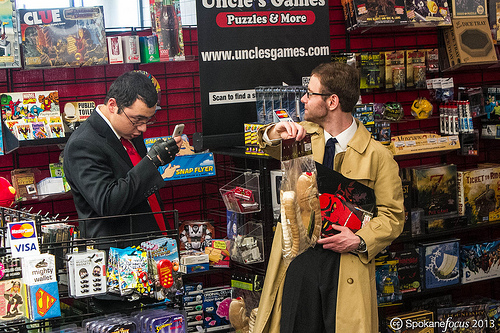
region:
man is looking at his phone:
[63, 71, 184, 241]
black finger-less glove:
[148, 138, 180, 166]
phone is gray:
[173, 121, 185, 136]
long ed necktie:
[121, 135, 170, 229]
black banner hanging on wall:
[196, 1, 333, 151]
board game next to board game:
[458, 168, 498, 229]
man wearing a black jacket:
[64, 74, 172, 246]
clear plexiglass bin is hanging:
[219, 170, 264, 215]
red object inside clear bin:
[233, 186, 253, 204]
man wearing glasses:
[61, 72, 171, 242]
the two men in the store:
[62, 60, 404, 331]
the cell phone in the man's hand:
[172, 123, 184, 137]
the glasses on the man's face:
[112, 98, 157, 126]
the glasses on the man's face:
[303, 87, 338, 98]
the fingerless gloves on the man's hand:
[147, 138, 179, 167]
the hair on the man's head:
[310, 60, 360, 110]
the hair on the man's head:
[105, 70, 159, 114]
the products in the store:
[0, 0, 498, 331]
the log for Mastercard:
[8, 221, 34, 237]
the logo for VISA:
[10, 240, 36, 252]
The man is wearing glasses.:
[253, 51, 408, 263]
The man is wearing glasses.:
[53, 63, 193, 232]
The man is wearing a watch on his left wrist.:
[253, 58, 403, 264]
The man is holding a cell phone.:
[63, 57, 194, 225]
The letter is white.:
[196, 45, 213, 65]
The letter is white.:
[233, 46, 243, 61]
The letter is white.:
[239, 45, 248, 61]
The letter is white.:
[247, 47, 254, 60]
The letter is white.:
[270, 45, 278, 65]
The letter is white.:
[275, 45, 285, 61]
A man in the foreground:
[224, 40, 409, 331]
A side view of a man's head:
[296, 48, 364, 141]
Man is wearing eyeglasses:
[297, 83, 336, 105]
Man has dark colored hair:
[301, 53, 373, 122]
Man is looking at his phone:
[57, 66, 202, 248]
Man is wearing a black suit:
[55, 101, 194, 249]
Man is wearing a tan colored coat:
[243, 99, 407, 331]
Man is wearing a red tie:
[115, 133, 180, 241]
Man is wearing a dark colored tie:
[315, 133, 343, 173]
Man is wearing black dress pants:
[278, 243, 350, 331]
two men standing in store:
[20, 0, 485, 329]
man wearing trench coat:
[235, 120, 397, 329]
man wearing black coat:
[51, 95, 158, 255]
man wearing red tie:
[111, 113, 167, 242]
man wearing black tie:
[305, 132, 342, 199]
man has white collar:
[305, 116, 362, 170]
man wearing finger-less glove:
[140, 123, 197, 173]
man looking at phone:
[86, 63, 216, 160]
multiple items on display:
[5, 168, 271, 330]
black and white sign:
[158, 0, 360, 141]